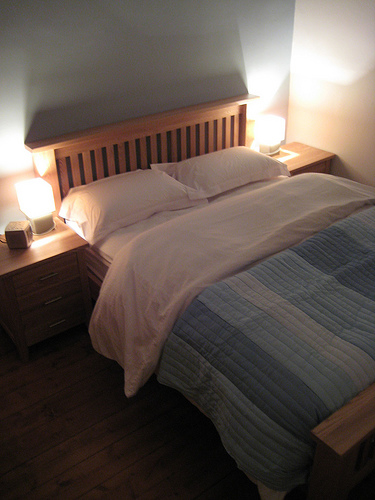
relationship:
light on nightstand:
[13, 176, 60, 232] [0, 214, 92, 361]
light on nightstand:
[256, 110, 285, 157] [269, 141, 335, 174]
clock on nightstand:
[5, 220, 34, 247] [0, 214, 92, 361]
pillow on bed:
[58, 168, 207, 247] [27, 90, 374, 500]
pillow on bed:
[150, 144, 292, 200] [27, 90, 374, 500]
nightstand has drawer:
[0, 214, 92, 361] [25, 305, 87, 346]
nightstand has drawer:
[0, 214, 92, 361] [20, 273, 89, 324]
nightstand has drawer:
[0, 214, 92, 361] [12, 251, 84, 295]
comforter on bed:
[89, 173, 375, 490] [27, 90, 374, 500]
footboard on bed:
[302, 382, 374, 498] [27, 90, 374, 500]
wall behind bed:
[0, 0, 300, 236] [27, 90, 374, 500]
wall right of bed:
[286, 1, 373, 188] [27, 90, 374, 500]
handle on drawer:
[48, 317, 66, 330] [25, 305, 87, 346]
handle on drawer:
[46, 293, 63, 304] [20, 273, 89, 324]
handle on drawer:
[41, 271, 57, 283] [12, 251, 84, 295]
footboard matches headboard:
[302, 382, 374, 498] [23, 94, 261, 224]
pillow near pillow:
[58, 168, 207, 247] [150, 144, 292, 200]